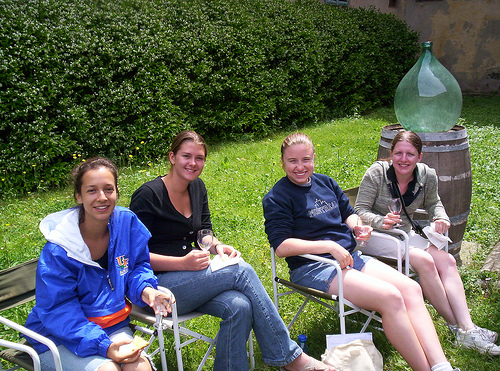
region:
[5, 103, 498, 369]
Four women holding glasses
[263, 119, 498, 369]
two women wearing shorts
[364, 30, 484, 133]
an empty glass bottle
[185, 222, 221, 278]
a right hand holding a glass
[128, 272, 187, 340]
a left hand holding a glass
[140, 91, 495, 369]
one woman wearing jeans and two women wearing shorts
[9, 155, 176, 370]
A woman seated wearing a blue jacket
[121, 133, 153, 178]
weeds with yellow flowers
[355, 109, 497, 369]
a woman holding a glass and a napkin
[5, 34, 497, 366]
four female friends relaxing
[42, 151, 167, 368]
person sitting on chair in yard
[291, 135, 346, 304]
person sitting on chair in yard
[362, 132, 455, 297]
person sitting on chair in yard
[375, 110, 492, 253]
wooden barrel behind woman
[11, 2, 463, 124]
thick hedges growing around yard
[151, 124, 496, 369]
tall grass growing in yard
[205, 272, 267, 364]
blue denim jeans on woman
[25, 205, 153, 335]
blue jacket on woman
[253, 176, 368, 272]
blue sweater on woman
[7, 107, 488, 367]
four women seating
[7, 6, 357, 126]
it is a big plant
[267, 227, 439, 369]
lady seating on the chair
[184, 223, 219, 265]
lady holding glass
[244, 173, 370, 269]
lady wearing blue shirt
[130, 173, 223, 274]
lady wearing black shirt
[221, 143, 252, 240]
it is a green grass